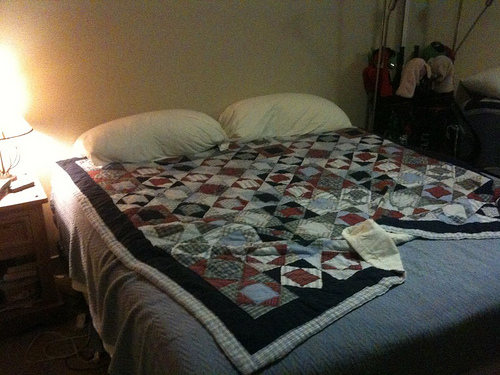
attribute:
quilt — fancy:
[148, 269, 334, 366]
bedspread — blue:
[56, 138, 496, 373]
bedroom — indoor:
[87, 61, 419, 294]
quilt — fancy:
[62, 76, 499, 366]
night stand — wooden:
[2, 171, 67, 336]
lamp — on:
[0, 61, 32, 186]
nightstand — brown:
[3, 168, 73, 330]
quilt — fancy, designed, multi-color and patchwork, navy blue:
[56, 123, 498, 373]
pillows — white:
[67, 99, 360, 134]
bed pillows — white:
[67, 85, 375, 170]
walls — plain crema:
[60, 24, 407, 90]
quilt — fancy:
[179, 218, 339, 271]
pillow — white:
[75, 108, 228, 169]